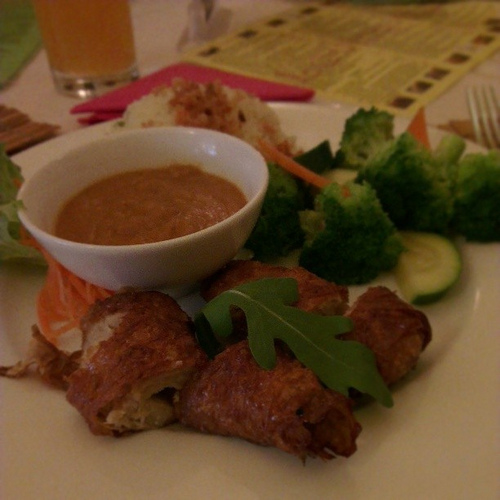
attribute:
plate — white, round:
[365, 261, 495, 488]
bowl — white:
[32, 144, 245, 270]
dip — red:
[69, 170, 217, 241]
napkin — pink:
[110, 47, 288, 111]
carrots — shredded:
[30, 261, 107, 331]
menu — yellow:
[218, 6, 485, 109]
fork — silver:
[463, 80, 499, 156]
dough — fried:
[84, 306, 283, 430]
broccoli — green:
[327, 137, 445, 247]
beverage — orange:
[47, 6, 126, 72]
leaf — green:
[221, 277, 379, 388]